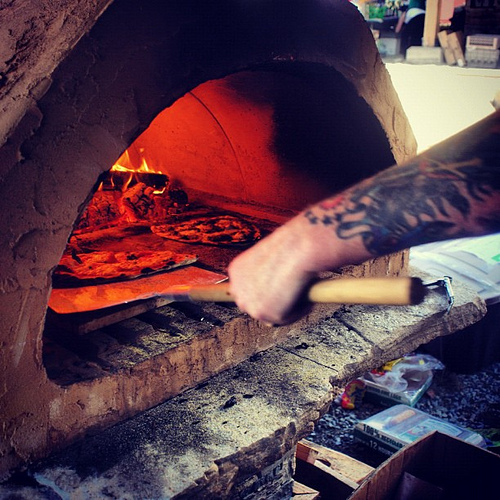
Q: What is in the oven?
A: Pizza.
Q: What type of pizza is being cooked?
A: Brick oven.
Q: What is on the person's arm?
A: Tattoo.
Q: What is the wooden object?
A: Paddle.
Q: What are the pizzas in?
A: Oven.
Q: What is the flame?
A: Fire.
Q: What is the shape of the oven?
A: Dome.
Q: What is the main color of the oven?
A: Brown.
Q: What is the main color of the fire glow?
A: Red.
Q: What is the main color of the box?
A: Brown.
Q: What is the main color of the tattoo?
A: Black.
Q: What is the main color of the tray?
A: Brown.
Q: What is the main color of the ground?
A: Gray.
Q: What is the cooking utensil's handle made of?
A: Wood.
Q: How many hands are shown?
A: 1.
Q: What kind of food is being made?
A: Pizza.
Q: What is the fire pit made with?
A: Concrete.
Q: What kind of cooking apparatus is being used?
A: Brick oven.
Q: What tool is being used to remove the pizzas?
A: Spatula.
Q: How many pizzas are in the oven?
A: 2.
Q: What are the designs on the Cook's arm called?
A: Tattoos.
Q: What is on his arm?
A: Tattoos.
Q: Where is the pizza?
A: In the oven.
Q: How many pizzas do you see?
A: 2.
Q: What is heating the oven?
A: Fire.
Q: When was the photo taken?
A: During daylight hours.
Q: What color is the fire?
A: Red and orange.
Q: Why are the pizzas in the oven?
A: To cook.